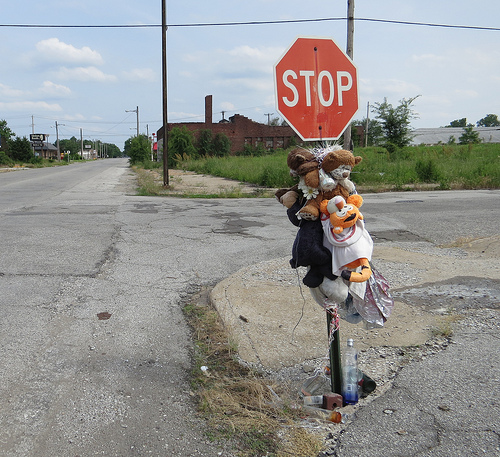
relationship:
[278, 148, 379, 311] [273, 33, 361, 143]
stuffed animals on sign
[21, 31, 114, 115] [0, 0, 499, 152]
clouds on blue sky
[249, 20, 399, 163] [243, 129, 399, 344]
stuffed animals on stop sign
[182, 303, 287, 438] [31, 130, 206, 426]
grass by sidewalk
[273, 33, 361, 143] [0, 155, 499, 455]
sign on street